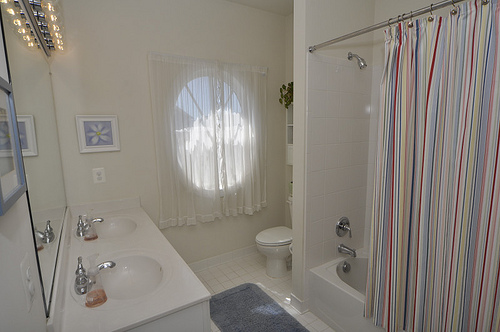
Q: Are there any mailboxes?
A: No, there are no mailboxes.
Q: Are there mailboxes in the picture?
A: No, there are no mailboxes.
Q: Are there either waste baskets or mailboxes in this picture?
A: No, there are no mailboxes or waste baskets.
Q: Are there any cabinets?
A: Yes, there is a cabinet.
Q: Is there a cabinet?
A: Yes, there is a cabinet.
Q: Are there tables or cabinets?
A: Yes, there is a cabinet.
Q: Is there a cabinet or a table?
A: Yes, there is a cabinet.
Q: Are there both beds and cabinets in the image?
A: No, there is a cabinet but no beds.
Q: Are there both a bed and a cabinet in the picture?
A: No, there is a cabinet but no beds.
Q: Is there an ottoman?
A: No, there are no ottomen.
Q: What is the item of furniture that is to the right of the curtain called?
A: The piece of furniture is a cabinet.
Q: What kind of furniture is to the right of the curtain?
A: The piece of furniture is a cabinet.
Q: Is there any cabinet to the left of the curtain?
A: No, the cabinet is to the right of the curtain.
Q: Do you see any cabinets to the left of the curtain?
A: No, the cabinet is to the right of the curtain.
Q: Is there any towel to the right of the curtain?
A: No, there is a cabinet to the right of the curtain.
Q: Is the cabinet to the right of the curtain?
A: Yes, the cabinet is to the right of the curtain.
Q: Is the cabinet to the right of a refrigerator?
A: No, the cabinet is to the right of the curtain.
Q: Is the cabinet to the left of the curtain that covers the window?
A: No, the cabinet is to the right of the curtain.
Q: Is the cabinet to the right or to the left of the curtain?
A: The cabinet is to the right of the curtain.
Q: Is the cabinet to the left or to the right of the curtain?
A: The cabinet is to the right of the curtain.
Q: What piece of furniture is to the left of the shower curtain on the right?
A: The piece of furniture is a cabinet.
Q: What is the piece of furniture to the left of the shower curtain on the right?
A: The piece of furniture is a cabinet.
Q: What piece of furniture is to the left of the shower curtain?
A: The piece of furniture is a cabinet.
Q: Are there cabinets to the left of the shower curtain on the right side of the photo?
A: Yes, there is a cabinet to the left of the shower curtain.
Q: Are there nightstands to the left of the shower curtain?
A: No, there is a cabinet to the left of the shower curtain.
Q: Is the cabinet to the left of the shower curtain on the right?
A: Yes, the cabinet is to the left of the shower curtain.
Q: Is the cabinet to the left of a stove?
A: No, the cabinet is to the left of the shower curtain.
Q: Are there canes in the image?
A: No, there are no canes.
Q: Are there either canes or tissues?
A: No, there are no canes or tissues.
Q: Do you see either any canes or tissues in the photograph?
A: No, there are no canes or tissues.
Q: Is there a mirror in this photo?
A: Yes, there is a mirror.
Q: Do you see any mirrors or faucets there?
A: Yes, there is a mirror.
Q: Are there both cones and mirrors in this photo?
A: No, there is a mirror but no cones.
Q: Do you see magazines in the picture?
A: No, there are no magazines.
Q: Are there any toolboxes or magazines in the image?
A: No, there are no magazines or toolboxes.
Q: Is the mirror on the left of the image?
A: Yes, the mirror is on the left of the image.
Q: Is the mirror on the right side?
A: No, the mirror is on the left of the image.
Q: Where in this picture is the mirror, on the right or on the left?
A: The mirror is on the left of the image.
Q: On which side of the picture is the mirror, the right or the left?
A: The mirror is on the left of the image.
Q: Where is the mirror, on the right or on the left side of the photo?
A: The mirror is on the left of the image.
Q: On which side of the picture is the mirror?
A: The mirror is on the left of the image.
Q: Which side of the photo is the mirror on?
A: The mirror is on the left of the image.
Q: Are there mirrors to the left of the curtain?
A: Yes, there is a mirror to the left of the curtain.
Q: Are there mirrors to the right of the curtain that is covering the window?
A: No, the mirror is to the left of the curtain.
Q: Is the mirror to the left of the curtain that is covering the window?
A: Yes, the mirror is to the left of the curtain.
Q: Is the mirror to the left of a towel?
A: No, the mirror is to the left of the curtain.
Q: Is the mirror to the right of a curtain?
A: No, the mirror is to the left of a curtain.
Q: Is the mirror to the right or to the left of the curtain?
A: The mirror is to the left of the curtain.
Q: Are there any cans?
A: No, there are no cans.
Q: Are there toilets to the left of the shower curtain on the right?
A: Yes, there is a toilet to the left of the shower curtain.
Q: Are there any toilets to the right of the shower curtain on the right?
A: No, the toilet is to the left of the shower curtain.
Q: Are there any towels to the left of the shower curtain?
A: No, there is a toilet to the left of the shower curtain.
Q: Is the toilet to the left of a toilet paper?
A: No, the toilet is to the left of a shower curtain.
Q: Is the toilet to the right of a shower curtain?
A: No, the toilet is to the left of a shower curtain.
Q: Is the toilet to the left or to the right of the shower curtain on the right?
A: The toilet is to the left of the shower curtain.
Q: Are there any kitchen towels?
A: No, there are no kitchen towels.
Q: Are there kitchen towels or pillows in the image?
A: No, there are no kitchen towels or pillows.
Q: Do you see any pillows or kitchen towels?
A: No, there are no kitchen towels or pillows.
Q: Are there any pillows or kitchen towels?
A: No, there are no kitchen towels or pillows.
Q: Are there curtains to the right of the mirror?
A: Yes, there is a curtain to the right of the mirror.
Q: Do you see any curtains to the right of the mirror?
A: Yes, there is a curtain to the right of the mirror.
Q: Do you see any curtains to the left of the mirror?
A: No, the curtain is to the right of the mirror.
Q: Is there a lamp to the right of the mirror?
A: No, there is a curtain to the right of the mirror.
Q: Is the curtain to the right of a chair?
A: No, the curtain is to the right of the mirror.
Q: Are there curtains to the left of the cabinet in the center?
A: Yes, there is a curtain to the left of the cabinet.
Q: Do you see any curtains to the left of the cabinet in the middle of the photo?
A: Yes, there is a curtain to the left of the cabinet.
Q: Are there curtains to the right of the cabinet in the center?
A: No, the curtain is to the left of the cabinet.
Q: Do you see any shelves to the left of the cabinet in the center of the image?
A: No, there is a curtain to the left of the cabinet.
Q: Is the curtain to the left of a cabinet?
A: Yes, the curtain is to the left of a cabinet.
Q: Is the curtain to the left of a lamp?
A: No, the curtain is to the left of a cabinet.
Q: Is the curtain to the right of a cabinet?
A: No, the curtain is to the left of a cabinet.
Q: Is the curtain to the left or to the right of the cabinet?
A: The curtain is to the left of the cabinet.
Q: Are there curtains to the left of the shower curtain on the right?
A: Yes, there is a curtain to the left of the shower curtain.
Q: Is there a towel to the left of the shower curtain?
A: No, there is a curtain to the left of the shower curtain.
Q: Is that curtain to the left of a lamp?
A: No, the curtain is to the left of the shower curtain.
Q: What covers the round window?
A: The curtain covers the window.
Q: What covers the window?
A: The curtain covers the window.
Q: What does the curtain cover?
A: The curtain covers the window.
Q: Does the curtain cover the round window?
A: Yes, the curtain covers the window.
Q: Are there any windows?
A: Yes, there is a window.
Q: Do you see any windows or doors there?
A: Yes, there is a window.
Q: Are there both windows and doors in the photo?
A: No, there is a window but no doors.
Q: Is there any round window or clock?
A: Yes, there is a round window.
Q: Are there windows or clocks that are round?
A: Yes, the window is round.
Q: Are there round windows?
A: Yes, there is a round window.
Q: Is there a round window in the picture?
A: Yes, there is a round window.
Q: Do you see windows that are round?
A: Yes, there is a window that is round.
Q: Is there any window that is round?
A: Yes, there is a window that is round.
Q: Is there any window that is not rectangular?
A: Yes, there is a round window.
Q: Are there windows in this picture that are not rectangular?
A: Yes, there is a round window.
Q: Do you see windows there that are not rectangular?
A: Yes, there is a round window.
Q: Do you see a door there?
A: No, there are no doors.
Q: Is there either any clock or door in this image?
A: No, there are no doors or clocks.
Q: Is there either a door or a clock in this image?
A: No, there are no doors or clocks.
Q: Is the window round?
A: Yes, the window is round.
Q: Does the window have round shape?
A: Yes, the window is round.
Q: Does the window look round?
A: Yes, the window is round.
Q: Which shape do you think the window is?
A: The window is round.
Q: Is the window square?
A: No, the window is round.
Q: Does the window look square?
A: No, the window is round.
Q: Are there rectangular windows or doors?
A: No, there is a window but it is round.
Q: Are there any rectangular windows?
A: No, there is a window but it is round.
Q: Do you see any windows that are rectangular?
A: No, there is a window but it is round.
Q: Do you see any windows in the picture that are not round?
A: No, there is a window but it is round.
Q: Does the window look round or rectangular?
A: The window is round.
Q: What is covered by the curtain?
A: The window is covered by the curtain.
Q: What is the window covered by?
A: The window is covered by the curtain.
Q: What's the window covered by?
A: The window is covered by the curtain.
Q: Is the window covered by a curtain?
A: Yes, the window is covered by a curtain.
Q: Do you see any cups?
A: No, there are no cups.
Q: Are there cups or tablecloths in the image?
A: No, there are no cups or tablecloths.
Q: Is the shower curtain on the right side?
A: Yes, the shower curtain is on the right of the image.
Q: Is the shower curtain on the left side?
A: No, the shower curtain is on the right of the image.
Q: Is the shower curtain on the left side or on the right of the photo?
A: The shower curtain is on the right of the image.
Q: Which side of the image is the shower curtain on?
A: The shower curtain is on the right of the image.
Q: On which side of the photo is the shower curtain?
A: The shower curtain is on the right of the image.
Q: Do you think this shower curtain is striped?
A: Yes, the shower curtain is striped.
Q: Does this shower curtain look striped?
A: Yes, the shower curtain is striped.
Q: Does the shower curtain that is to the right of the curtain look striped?
A: Yes, the shower curtain is striped.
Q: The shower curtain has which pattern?
A: The shower curtain is striped.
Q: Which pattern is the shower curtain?
A: The shower curtain is striped.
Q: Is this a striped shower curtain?
A: Yes, this is a striped shower curtain.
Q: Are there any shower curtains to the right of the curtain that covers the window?
A: Yes, there is a shower curtain to the right of the curtain.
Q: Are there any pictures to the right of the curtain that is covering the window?
A: No, there is a shower curtain to the right of the curtain.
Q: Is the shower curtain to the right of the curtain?
A: Yes, the shower curtain is to the right of the curtain.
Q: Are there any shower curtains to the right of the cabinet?
A: Yes, there is a shower curtain to the right of the cabinet.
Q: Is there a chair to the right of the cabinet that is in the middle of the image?
A: No, there is a shower curtain to the right of the cabinet.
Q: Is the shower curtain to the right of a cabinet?
A: Yes, the shower curtain is to the right of a cabinet.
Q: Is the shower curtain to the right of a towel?
A: No, the shower curtain is to the right of a cabinet.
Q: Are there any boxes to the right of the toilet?
A: No, there is a shower curtain to the right of the toilet.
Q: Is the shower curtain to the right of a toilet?
A: Yes, the shower curtain is to the right of a toilet.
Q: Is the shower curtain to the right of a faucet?
A: No, the shower curtain is to the right of a toilet.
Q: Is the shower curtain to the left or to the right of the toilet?
A: The shower curtain is to the right of the toilet.